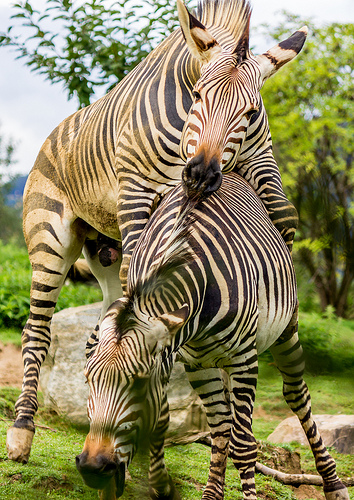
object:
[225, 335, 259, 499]
leg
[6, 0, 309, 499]
animal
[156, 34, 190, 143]
stripes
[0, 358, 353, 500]
grass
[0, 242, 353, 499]
ground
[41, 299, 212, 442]
rock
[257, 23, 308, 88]
ear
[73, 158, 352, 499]
zebra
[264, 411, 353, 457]
rock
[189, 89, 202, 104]
eyes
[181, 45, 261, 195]
face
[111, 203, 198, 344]
mane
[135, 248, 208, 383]
neck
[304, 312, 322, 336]
leaves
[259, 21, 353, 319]
tree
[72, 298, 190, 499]
head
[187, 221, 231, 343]
stripes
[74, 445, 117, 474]
nose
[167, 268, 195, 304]
fur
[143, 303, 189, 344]
ear